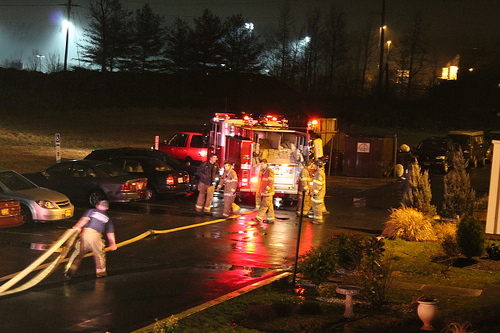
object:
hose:
[128, 187, 237, 284]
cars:
[0, 170, 75, 228]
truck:
[201, 111, 326, 201]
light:
[246, 175, 259, 185]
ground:
[0, 91, 499, 332]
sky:
[0, 0, 499, 74]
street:
[0, 173, 396, 333]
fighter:
[62, 199, 120, 279]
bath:
[163, 244, 203, 278]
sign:
[351, 141, 373, 155]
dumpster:
[303, 116, 401, 180]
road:
[0, 150, 426, 332]